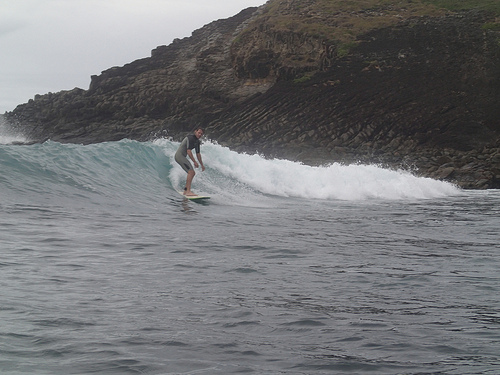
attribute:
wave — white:
[252, 146, 311, 190]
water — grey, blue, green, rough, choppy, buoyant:
[231, 223, 341, 304]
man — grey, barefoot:
[168, 122, 211, 192]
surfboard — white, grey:
[190, 194, 214, 204]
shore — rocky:
[274, 122, 445, 190]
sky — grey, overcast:
[21, 8, 85, 53]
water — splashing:
[1, 125, 21, 135]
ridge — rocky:
[94, 57, 121, 74]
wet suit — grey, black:
[167, 134, 206, 177]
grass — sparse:
[316, 19, 360, 41]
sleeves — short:
[183, 137, 197, 152]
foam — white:
[247, 151, 291, 187]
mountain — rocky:
[164, 1, 401, 123]